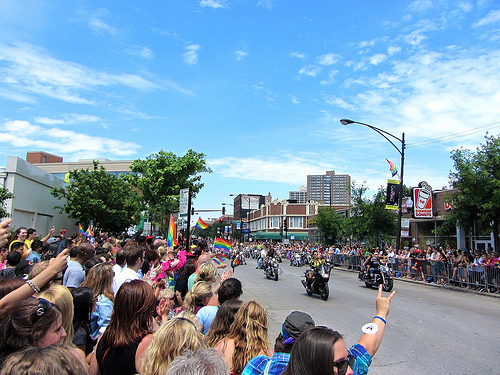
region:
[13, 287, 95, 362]
the head of a woman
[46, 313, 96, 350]
the nose of a woman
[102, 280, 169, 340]
the hair of a woman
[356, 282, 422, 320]
the hand of a woman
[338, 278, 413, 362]
the arm of a woman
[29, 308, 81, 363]
the face of a woman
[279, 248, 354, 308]
a person on a bike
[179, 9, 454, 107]
clouds in the sky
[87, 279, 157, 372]
person is standing next to person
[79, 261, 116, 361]
person is standing next to person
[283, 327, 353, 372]
person is standing next to person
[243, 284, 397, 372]
person is standing next to person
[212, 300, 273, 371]
person is standing next to person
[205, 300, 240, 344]
person is standing next to person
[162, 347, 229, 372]
person is standing next to person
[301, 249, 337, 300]
person riding motorcycle in parade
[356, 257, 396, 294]
person riding motorcycle in parade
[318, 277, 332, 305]
a tire on a motorcycle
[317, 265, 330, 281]
a light on the motorcycle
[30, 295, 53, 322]
sunglasses on a womans head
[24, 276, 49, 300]
a bracelet on an arm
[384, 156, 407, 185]
a flag on a pole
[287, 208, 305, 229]
windows on a building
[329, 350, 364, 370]
woman wearing sunglasses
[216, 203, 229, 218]
a traffic light above the street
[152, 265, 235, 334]
people watching the motorcycles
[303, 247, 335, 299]
this is a motorbike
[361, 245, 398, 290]
this is a motorbike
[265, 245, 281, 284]
this is a motorbike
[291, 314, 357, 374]
this is a head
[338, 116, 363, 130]
this is a light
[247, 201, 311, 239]
this is a building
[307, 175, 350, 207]
this is a building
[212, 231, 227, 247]
this is a flag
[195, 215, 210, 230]
this is a flag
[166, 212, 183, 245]
this is a flag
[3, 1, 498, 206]
clouds in daytime sky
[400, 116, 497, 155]
wires suspended on pole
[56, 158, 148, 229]
green leaves on trees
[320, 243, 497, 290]
crowd of people behind fence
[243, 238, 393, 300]
motor bikes in a parade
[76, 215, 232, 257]
rainbow flags over crowd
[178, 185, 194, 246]
sign on black pole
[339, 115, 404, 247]
street light on pole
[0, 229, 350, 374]
people along parade route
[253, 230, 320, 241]
green awning on building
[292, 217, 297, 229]
A window on the side of a building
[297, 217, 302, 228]
A window on the side of a building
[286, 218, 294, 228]
A window on the side of a building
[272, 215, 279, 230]
A window on the side of a building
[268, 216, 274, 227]
A window on the side of a building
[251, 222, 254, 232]
A window on the side of a building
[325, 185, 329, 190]
A window on the side of a building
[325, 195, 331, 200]
A window on the side of a building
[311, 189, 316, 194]
A window on the side of a building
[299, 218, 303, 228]
A window on a building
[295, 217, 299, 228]
A window on a building